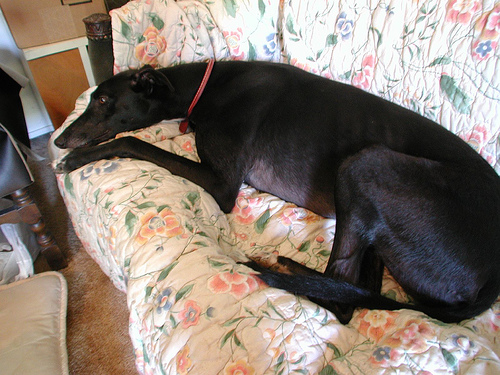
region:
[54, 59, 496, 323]
a black dog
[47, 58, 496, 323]
a black dog laying on a couch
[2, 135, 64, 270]
the leg of a table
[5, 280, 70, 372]
a pink couch on the floor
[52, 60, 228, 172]
a dog wearing a red collar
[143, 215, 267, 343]
floral print on the couch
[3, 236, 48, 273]
a bag on the floor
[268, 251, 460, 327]
the tail of the dog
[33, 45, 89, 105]
the wall behind the dog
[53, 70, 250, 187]
a dog laying down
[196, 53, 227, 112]
a red collar on a dog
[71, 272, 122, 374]
brown carpe on the floor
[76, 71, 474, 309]
a dog with shiny black coat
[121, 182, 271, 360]
a floral cover on sofa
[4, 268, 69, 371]
a beige pillow on floor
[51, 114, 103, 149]
a long black snout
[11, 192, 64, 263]
a dark brown wooden chair leg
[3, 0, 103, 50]
a cardboard box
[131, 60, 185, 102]
a floppy black ear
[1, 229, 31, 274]
a white plastic bag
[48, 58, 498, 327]
Black dog with brown eyes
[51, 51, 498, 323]
Dog wearing red collar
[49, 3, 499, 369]
Dog resting on flowered sofa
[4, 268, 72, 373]
Square tan cushion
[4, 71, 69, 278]
Brown wood chair leg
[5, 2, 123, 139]
Two tone tan wall with white trim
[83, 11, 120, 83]
Brown canister with ornate wood top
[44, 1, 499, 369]
Floral sofa with shades of green, blue and peach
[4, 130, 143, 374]
Light tan carpet with short nap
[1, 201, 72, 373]
White plastic bag beside seat cushion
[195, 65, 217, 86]
a red collar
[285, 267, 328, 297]
the tail of the dog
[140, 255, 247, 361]
the couch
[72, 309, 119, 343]
the carpet is brown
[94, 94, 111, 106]
the dogs eye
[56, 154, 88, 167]
the dogs paw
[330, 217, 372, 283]
the dogs back leg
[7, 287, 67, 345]
a pillow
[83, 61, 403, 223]
the dog is black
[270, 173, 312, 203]
the dogs stomach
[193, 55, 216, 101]
This dog has a very red collar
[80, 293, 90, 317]
There is light beige carpet that this house has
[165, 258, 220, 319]
This quilt has flowers and vines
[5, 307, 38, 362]
There is a cream pillow on the floor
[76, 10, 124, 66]
There is a couch that has an olive arm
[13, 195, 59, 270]
There are a wooden post here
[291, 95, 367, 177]
This dog has a very black color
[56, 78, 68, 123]
The door here is a light wooden color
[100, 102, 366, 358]
Jackson Mingus has taken this photo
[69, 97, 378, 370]
The season in this was taken was summer